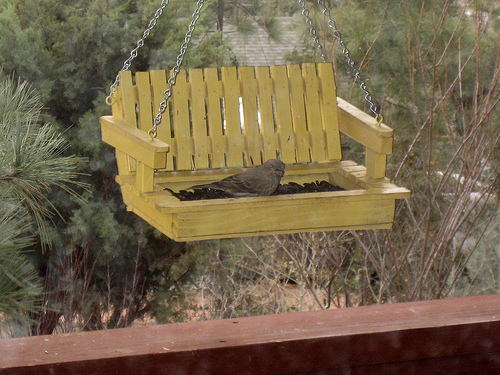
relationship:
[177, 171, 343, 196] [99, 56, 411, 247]
bird food in bird feeder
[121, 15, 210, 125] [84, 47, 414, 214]
chains holding bench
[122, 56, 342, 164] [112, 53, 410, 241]
back of bench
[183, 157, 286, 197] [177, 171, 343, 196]
bird eating bird food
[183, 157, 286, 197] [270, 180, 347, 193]
bird eating food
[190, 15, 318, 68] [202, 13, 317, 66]
roof of house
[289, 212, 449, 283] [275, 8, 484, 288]
branches of bush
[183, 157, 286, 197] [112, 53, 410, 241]
bird resting on bench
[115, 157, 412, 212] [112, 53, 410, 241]
seat of bench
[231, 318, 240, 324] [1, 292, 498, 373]
hole in wood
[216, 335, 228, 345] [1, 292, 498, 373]
hole in wood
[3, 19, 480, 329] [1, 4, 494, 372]
backyard in area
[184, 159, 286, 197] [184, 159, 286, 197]
bird a bird